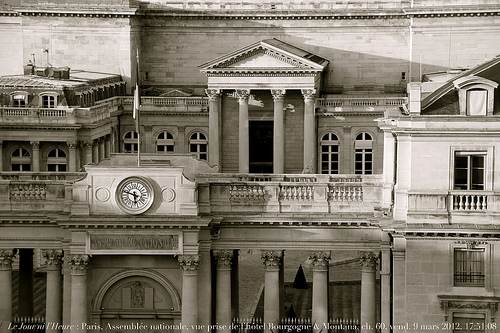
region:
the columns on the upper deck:
[209, 85, 317, 194]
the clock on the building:
[114, 172, 154, 217]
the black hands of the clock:
[126, 187, 142, 205]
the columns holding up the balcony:
[211, 235, 386, 332]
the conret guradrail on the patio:
[222, 175, 377, 216]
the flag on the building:
[123, 57, 146, 132]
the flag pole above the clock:
[124, 36, 150, 175]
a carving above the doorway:
[122, 277, 154, 310]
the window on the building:
[453, 150, 488, 220]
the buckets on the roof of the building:
[22, 58, 75, 82]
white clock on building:
[117, 174, 163, 217]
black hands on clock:
[108, 181, 157, 211]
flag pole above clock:
[127, 54, 152, 161]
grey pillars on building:
[207, 81, 314, 169]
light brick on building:
[135, 24, 208, 86]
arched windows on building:
[324, 129, 371, 168]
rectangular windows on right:
[435, 147, 499, 220]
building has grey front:
[5, 46, 455, 331]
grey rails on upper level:
[236, 181, 366, 203]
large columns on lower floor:
[211, 241, 378, 331]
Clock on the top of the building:
[116, 176, 155, 213]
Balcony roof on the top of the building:
[2, 163, 383, 212]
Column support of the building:
[260, 248, 282, 332]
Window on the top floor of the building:
[447, 144, 491, 211]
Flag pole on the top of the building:
[131, 48, 143, 167]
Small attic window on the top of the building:
[457, 82, 494, 116]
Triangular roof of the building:
[197, 36, 326, 72]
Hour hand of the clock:
[132, 190, 138, 203]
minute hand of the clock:
[121, 188, 140, 197]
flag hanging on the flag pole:
[130, 48, 143, 123]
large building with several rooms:
[0, 33, 485, 306]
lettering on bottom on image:
[5, 304, 484, 331]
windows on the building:
[449, 148, 489, 193]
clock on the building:
[108, 177, 160, 214]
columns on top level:
[198, 85, 325, 173]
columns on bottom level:
[218, 241, 399, 331]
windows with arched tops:
[321, 123, 373, 175]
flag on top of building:
[126, 40, 149, 165]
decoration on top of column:
[202, 79, 324, 97]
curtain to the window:
[460, 252, 485, 280]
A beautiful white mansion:
[15, 13, 472, 330]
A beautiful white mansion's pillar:
[304, 245, 331, 332]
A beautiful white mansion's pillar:
[255, 245, 288, 332]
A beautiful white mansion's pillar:
[217, 237, 245, 328]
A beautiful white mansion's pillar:
[60, 234, 95, 332]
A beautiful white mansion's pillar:
[297, 87, 329, 173]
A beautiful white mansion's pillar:
[204, 81, 226, 171]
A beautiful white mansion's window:
[442, 148, 493, 198]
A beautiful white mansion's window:
[351, 131, 379, 173]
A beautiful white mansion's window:
[315, 129, 339, 177]